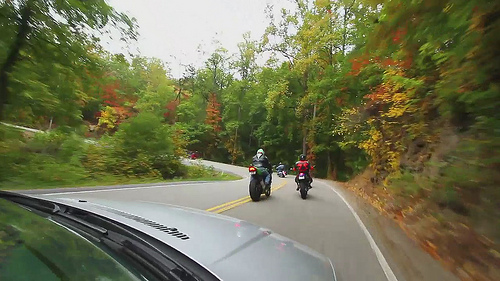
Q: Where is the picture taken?
A: On the road.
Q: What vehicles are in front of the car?
A: Motorcycles.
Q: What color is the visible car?
A: Silver.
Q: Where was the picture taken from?
A: A car.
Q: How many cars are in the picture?
A: 1.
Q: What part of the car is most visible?
A: The hood.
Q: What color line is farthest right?
A: White.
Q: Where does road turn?
A: Left.